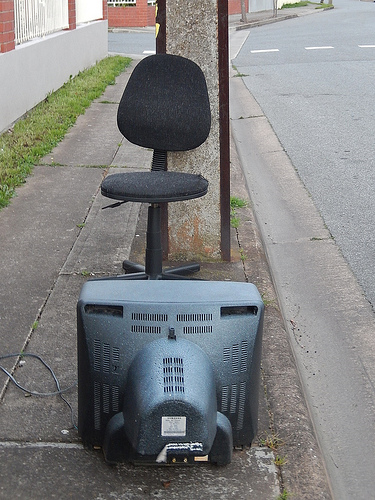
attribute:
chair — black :
[101, 51, 214, 279]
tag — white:
[160, 417, 186, 437]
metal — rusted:
[213, 4, 240, 270]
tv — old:
[72, 280, 263, 473]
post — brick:
[156, 2, 241, 253]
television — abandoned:
[72, 278, 262, 468]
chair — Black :
[87, 52, 208, 280]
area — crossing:
[137, 37, 369, 56]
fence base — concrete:
[0, 17, 108, 132]